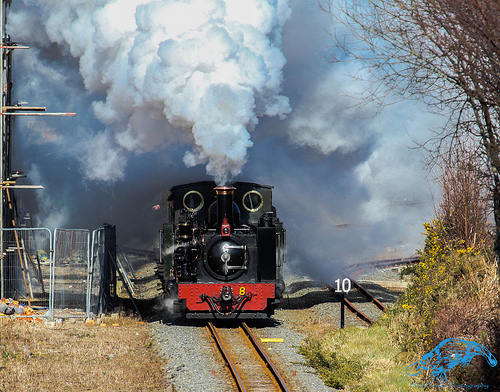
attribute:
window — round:
[246, 187, 261, 215]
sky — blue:
[16, 3, 436, 277]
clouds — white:
[15, 13, 433, 253]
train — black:
[134, 169, 301, 322]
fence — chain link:
[5, 230, 117, 316]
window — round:
[139, 193, 253, 215]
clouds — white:
[81, 150, 133, 188]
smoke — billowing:
[84, 3, 304, 184]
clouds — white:
[315, 76, 387, 167]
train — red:
[154, 159, 291, 331]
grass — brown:
[1, 246, 166, 390]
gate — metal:
[2, 219, 122, 321]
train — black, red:
[166, 172, 285, 319]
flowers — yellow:
[379, 210, 498, 356]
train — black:
[135, 156, 333, 348]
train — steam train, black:
[152, 179, 292, 326]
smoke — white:
[11, 0, 289, 178]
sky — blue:
[10, 3, 493, 257]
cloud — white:
[9, 4, 292, 187]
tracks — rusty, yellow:
[212, 316, 284, 389]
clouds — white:
[273, 70, 426, 219]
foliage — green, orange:
[398, 204, 489, 371]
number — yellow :
[237, 284, 247, 296]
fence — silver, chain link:
[10, 227, 107, 315]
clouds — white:
[153, 24, 247, 94]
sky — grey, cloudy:
[31, 10, 362, 185]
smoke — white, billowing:
[53, 8, 292, 180]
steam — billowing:
[9, 5, 487, 272]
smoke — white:
[38, 0, 300, 187]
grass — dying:
[8, 315, 138, 390]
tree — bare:
[327, 4, 499, 237]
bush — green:
[390, 222, 483, 343]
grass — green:
[307, 331, 407, 389]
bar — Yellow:
[259, 335, 284, 342]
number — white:
[315, 264, 369, 299]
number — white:
[333, 273, 352, 293]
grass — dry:
[0, 299, 168, 390]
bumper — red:
[170, 280, 278, 314]